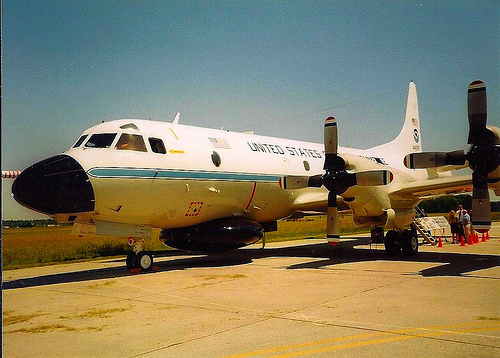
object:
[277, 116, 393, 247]
propeller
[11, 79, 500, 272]
airplane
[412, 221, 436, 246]
bridge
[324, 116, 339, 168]
blade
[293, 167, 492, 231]
wing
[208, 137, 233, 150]
american flag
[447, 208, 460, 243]
people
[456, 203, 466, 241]
people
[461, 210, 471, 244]
people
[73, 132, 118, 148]
window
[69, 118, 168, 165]
cockpit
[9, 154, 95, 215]
nose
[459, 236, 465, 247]
cones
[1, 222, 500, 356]
tarmac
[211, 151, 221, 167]
windows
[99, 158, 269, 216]
side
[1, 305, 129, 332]
stains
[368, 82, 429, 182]
tail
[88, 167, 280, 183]
stripe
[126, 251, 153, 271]
wheels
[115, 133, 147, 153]
window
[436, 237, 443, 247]
cone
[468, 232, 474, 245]
traffic cones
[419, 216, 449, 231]
literature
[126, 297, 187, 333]
plane